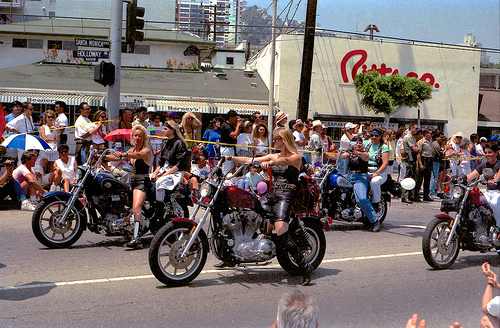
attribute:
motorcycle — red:
[148, 155, 326, 287]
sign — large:
[338, 49, 442, 89]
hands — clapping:
[480, 260, 500, 292]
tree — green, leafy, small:
[353, 68, 434, 120]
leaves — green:
[354, 71, 433, 114]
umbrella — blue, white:
[1, 133, 51, 152]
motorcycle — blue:
[321, 145, 388, 228]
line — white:
[0, 251, 424, 291]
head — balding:
[276, 288, 320, 327]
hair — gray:
[277, 288, 320, 327]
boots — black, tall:
[213, 229, 313, 287]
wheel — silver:
[157, 227, 204, 279]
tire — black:
[148, 221, 208, 287]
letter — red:
[340, 50, 367, 82]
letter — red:
[420, 73, 434, 91]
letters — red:
[339, 49, 435, 92]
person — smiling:
[453, 141, 500, 229]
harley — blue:
[31, 145, 195, 250]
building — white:
[252, 31, 482, 143]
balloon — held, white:
[256, 180, 268, 196]